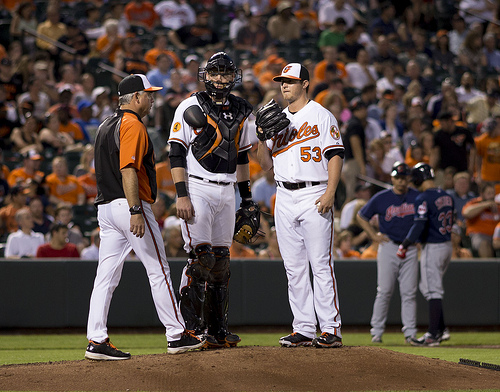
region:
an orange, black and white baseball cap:
[273, 60, 310, 85]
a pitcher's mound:
[0, 335, 497, 390]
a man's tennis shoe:
[160, 331, 205, 351]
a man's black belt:
[275, 177, 320, 187]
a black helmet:
[406, 160, 432, 187]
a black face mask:
[197, 61, 244, 101]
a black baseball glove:
[251, 95, 288, 140]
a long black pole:
[100, 59, 127, 81]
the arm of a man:
[317, 111, 349, 188]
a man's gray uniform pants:
[372, 238, 419, 338]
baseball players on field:
[12, 10, 430, 339]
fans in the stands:
[0, 39, 80, 161]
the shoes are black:
[274, 325, 336, 348]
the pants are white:
[295, 248, 327, 307]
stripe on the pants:
[144, 233, 181, 325]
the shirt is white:
[266, 155, 326, 176]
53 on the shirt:
[289, 132, 324, 168]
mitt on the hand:
[247, 103, 291, 138]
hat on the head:
[111, 70, 167, 90]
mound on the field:
[313, 355, 395, 378]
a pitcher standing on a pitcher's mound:
[257, 61, 347, 348]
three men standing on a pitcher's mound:
[85, 50, 345, 361]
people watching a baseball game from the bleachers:
[2, 0, 497, 257]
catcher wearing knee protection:
[181, 246, 234, 345]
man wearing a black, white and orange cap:
[116, 73, 161, 96]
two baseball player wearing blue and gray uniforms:
[357, 161, 455, 348]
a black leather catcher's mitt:
[257, 97, 289, 142]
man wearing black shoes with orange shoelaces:
[277, 329, 340, 346]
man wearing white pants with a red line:
[273, 186, 339, 336]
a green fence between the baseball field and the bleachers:
[3, 257, 499, 329]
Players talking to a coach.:
[85, 48, 354, 360]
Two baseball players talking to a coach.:
[83, 47, 348, 359]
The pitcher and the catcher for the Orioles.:
[167, 52, 347, 352]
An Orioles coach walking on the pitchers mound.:
[87, 71, 210, 359]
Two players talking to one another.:
[357, 158, 458, 346]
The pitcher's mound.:
[0, 342, 498, 391]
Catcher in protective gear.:
[167, 49, 259, 354]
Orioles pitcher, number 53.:
[252, 62, 348, 349]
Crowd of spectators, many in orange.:
[2, 28, 497, 261]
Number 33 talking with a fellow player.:
[355, 157, 457, 345]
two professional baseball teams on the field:
[1, 50, 498, 390]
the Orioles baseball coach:
[82, 72, 205, 360]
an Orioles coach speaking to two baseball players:
[82, 72, 208, 360]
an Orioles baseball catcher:
[165, 50, 261, 348]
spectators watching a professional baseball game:
[2, 2, 498, 255]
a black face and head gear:
[195, 50, 245, 105]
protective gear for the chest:
[182, 91, 254, 173]